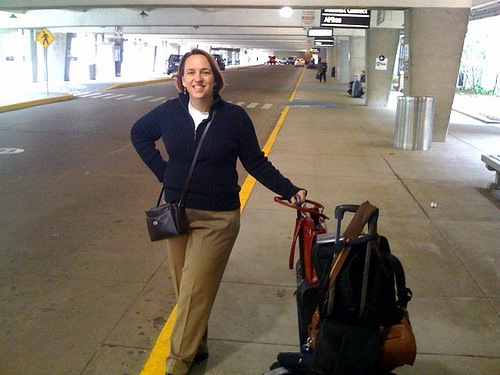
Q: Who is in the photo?
A: A woman.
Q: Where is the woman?
A: Drop-off and pick-up area.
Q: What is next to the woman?
A: Luggage.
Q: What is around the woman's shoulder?
A: Purse.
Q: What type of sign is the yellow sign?
A: Pedestrian crossing.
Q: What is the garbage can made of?
A: Metal.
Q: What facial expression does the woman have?
A: Happy and smiling.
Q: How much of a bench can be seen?
A: Corner.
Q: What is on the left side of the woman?
A: Road.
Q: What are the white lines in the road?
A: Crosswalk.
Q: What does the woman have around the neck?
A: Her purse.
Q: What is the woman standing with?
A: Suitcases.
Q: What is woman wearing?
A: Sweater.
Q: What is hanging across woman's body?
A: Purse.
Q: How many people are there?
A: One.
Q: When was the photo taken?
A: Afternoon.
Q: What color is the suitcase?
A: Black.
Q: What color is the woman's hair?
A: Brown.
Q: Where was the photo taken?
A: Airport.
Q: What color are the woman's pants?
A: Khaki.